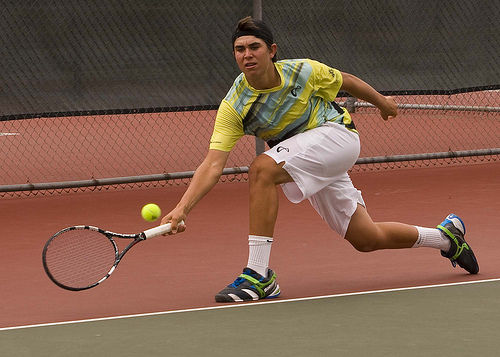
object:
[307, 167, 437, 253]
leg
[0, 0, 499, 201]
fence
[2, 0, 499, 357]
tennis court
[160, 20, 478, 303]
man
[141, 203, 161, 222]
tennis ball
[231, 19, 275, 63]
cap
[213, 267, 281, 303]
foot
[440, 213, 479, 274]
foot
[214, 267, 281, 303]
sneakers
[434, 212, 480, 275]
sneakers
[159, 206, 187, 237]
hand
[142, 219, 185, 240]
white handle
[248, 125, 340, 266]
leg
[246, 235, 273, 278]
sock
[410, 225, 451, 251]
sock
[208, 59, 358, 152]
shirt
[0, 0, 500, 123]
tarp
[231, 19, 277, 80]
head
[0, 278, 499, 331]
line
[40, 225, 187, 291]
racket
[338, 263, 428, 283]
ground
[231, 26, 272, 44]
headband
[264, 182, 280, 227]
muscle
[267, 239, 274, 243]
nike brand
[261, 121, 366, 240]
shorts